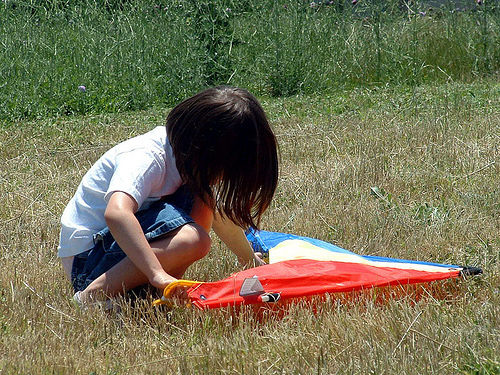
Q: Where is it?
A: This is at the field.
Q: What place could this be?
A: It is a field.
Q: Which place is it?
A: It is a field.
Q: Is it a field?
A: Yes, it is a field.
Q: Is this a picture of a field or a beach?
A: It is showing a field.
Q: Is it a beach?
A: No, it is a field.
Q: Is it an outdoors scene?
A: Yes, it is outdoors.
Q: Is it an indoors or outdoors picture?
A: It is outdoors.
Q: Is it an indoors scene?
A: No, it is outdoors.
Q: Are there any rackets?
A: No, there are no rackets.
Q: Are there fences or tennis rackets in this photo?
A: No, there are no tennis rackets or fences.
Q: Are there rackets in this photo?
A: No, there are no rackets.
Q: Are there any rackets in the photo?
A: No, there are no rackets.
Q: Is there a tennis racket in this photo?
A: No, there are no rackets.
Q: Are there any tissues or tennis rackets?
A: No, there are no tennis rackets or tissues.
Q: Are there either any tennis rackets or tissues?
A: No, there are no tennis rackets or tissues.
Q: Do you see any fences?
A: No, there are no fences.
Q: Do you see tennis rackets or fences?
A: No, there are no fences or tennis rackets.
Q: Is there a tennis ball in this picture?
A: No, there are no tennis balls.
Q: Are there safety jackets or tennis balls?
A: No, there are no tennis balls or safety jackets.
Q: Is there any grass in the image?
A: Yes, there is grass.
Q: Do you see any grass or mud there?
A: Yes, there is grass.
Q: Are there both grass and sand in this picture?
A: No, there is grass but no sand.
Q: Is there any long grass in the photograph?
A: Yes, there is long grass.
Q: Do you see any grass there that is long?
A: Yes, there is grass that is long.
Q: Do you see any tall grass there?
A: Yes, there is tall grass.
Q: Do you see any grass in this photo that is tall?
A: Yes, there is grass that is tall.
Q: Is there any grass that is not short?
A: Yes, there is tall grass.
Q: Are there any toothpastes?
A: No, there are no toothpastes.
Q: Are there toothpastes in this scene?
A: No, there are no toothpastes.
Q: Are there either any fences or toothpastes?
A: No, there are no toothpastes or fences.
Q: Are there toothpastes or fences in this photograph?
A: No, there are no toothpastes or fences.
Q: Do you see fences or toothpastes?
A: No, there are no toothpastes or fences.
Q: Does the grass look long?
A: Yes, the grass is long.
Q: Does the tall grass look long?
A: Yes, the grass is long.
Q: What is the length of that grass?
A: The grass is long.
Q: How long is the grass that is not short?
A: The grass is long.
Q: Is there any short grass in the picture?
A: No, there is grass but it is long.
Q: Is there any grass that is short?
A: No, there is grass but it is long.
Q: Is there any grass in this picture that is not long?
A: No, there is grass but it is long.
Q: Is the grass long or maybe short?
A: The grass is long.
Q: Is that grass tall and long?
A: Yes, the grass is tall and long.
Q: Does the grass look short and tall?
A: No, the grass is tall but long.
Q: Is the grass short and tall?
A: No, the grass is tall but long.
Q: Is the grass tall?
A: Yes, the grass is tall.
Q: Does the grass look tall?
A: Yes, the grass is tall.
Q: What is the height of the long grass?
A: The grass is tall.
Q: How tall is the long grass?
A: The grass is tall.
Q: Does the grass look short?
A: No, the grass is tall.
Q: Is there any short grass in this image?
A: No, there is grass but it is tall.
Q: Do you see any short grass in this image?
A: No, there is grass but it is tall.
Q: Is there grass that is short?
A: No, there is grass but it is tall.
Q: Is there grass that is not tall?
A: No, there is grass but it is tall.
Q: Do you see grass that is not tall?
A: No, there is grass but it is tall.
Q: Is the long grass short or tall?
A: The grass is tall.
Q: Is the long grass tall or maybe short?
A: The grass is tall.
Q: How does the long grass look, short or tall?
A: The grass is tall.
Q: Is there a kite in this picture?
A: Yes, there is a kite.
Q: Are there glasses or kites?
A: Yes, there is a kite.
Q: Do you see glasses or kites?
A: Yes, there is a kite.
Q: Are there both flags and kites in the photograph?
A: No, there is a kite but no flags.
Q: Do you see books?
A: No, there are no books.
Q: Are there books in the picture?
A: No, there are no books.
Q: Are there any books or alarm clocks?
A: No, there are no books or alarm clocks.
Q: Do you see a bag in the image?
A: No, there are no bags.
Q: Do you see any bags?
A: No, there are no bags.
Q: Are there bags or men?
A: No, there are no bags or men.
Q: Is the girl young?
A: Yes, the girl is young.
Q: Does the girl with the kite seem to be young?
A: Yes, the girl is young.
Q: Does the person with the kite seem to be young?
A: Yes, the girl is young.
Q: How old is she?
A: The girl is young.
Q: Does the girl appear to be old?
A: No, the girl is young.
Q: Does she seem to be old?
A: No, the girl is young.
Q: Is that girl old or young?
A: The girl is young.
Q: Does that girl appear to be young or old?
A: The girl is young.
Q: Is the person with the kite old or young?
A: The girl is young.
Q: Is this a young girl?
A: Yes, this is a young girl.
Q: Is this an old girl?
A: No, this is a young girl.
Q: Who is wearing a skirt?
A: The girl is wearing a skirt.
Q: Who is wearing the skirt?
A: The girl is wearing a skirt.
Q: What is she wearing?
A: The girl is wearing a skirt.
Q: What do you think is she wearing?
A: The girl is wearing a skirt.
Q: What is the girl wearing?
A: The girl is wearing a skirt.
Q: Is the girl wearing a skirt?
A: Yes, the girl is wearing a skirt.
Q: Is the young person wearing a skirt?
A: Yes, the girl is wearing a skirt.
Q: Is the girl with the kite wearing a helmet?
A: No, the girl is wearing a skirt.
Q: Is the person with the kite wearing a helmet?
A: No, the girl is wearing a skirt.